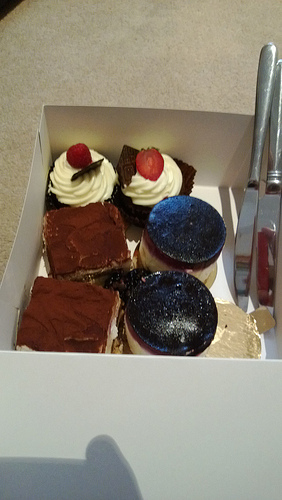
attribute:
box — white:
[0, 104, 281, 497]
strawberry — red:
[133, 147, 165, 182]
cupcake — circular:
[115, 146, 197, 229]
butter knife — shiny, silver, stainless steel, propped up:
[255, 59, 281, 317]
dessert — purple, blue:
[139, 196, 228, 283]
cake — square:
[41, 200, 133, 286]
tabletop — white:
[1, 2, 281, 284]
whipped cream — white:
[117, 152, 183, 205]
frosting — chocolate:
[43, 202, 131, 277]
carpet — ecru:
[1, 0, 281, 277]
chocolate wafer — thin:
[115, 143, 139, 188]